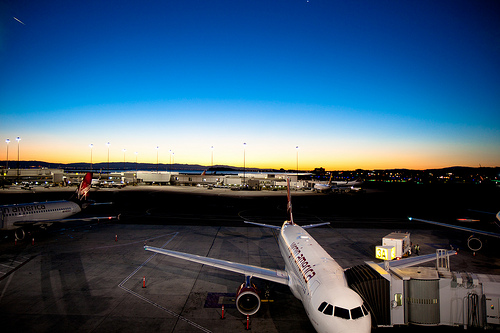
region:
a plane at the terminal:
[139, 177, 459, 329]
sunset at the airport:
[0, 101, 498, 218]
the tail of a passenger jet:
[277, 175, 297, 231]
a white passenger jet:
[140, 176, 461, 331]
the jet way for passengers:
[345, 259, 498, 331]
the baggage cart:
[357, 228, 415, 269]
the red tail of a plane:
[70, 165, 97, 213]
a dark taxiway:
[90, 185, 332, 261]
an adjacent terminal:
[0, 163, 340, 186]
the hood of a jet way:
[337, 260, 388, 323]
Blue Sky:
[19, 13, 486, 93]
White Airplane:
[153, 222, 381, 330]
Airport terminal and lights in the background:
[10, 175, 171, 190]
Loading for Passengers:
[358, 261, 488, 326]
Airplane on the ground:
[0, 191, 111, 242]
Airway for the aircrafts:
[0, 270, 170, 323]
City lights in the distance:
[320, 163, 496, 185]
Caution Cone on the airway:
[117, 265, 167, 305]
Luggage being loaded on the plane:
[375, 230, 420, 260]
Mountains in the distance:
[81, 162, 204, 170]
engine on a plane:
[231, 276, 271, 322]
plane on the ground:
[130, 171, 477, 332]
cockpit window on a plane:
[314, 298, 374, 321]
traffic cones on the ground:
[134, 272, 152, 299]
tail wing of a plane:
[277, 175, 304, 229]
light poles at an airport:
[232, 135, 254, 196]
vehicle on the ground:
[369, 225, 419, 269]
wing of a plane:
[135, 238, 292, 298]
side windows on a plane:
[49, 203, 76, 213]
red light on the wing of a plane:
[96, 208, 127, 223]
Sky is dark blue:
[3, 2, 498, 129]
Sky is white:
[4, 126, 492, 167]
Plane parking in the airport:
[114, 186, 462, 330]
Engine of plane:
[226, 279, 268, 321]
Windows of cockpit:
[314, 299, 376, 326]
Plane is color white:
[140, 169, 482, 331]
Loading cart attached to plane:
[339, 249, 496, 331]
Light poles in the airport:
[228, 136, 263, 187]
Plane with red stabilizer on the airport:
[5, 153, 130, 263]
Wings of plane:
[133, 231, 462, 284]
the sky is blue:
[75, 18, 250, 98]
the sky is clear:
[77, 20, 213, 94]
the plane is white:
[137, 189, 479, 330]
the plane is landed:
[132, 185, 464, 331]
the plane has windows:
[305, 282, 390, 329]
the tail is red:
[64, 161, 101, 206]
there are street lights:
[232, 134, 261, 196]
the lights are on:
[362, 227, 442, 296]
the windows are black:
[315, 288, 382, 328]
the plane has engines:
[222, 272, 281, 323]